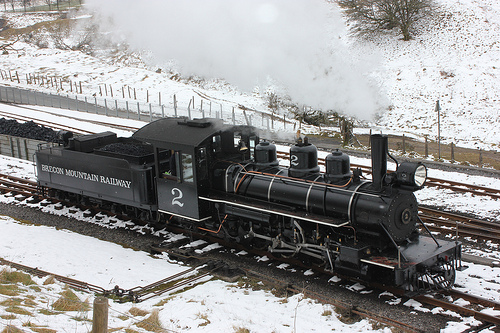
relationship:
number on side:
[168, 186, 186, 211] [154, 180, 198, 219]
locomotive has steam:
[36, 114, 465, 291] [69, 0, 393, 124]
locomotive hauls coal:
[36, 114, 465, 291] [92, 136, 173, 162]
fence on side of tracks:
[1, 86, 223, 120] [427, 175, 500, 200]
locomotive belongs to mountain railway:
[36, 114, 465, 291] [64, 165, 132, 190]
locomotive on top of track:
[36, 114, 465, 291] [0, 173, 499, 324]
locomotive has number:
[36, 114, 465, 291] [168, 186, 186, 211]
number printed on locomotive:
[168, 186, 186, 211] [36, 114, 465, 291]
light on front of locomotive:
[396, 162, 427, 190] [36, 114, 465, 291]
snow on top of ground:
[0, 220, 168, 285] [0, 255, 265, 331]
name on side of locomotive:
[64, 165, 132, 190] [36, 114, 465, 291]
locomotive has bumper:
[36, 114, 465, 291] [32, 144, 50, 196]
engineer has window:
[157, 148, 181, 183] [176, 151, 194, 184]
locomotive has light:
[36, 114, 465, 291] [396, 162, 427, 190]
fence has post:
[1, 86, 223, 120] [15, 70, 21, 86]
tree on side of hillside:
[337, 2, 437, 45] [343, 5, 499, 130]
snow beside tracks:
[0, 220, 168, 285] [427, 175, 500, 200]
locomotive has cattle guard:
[36, 114, 465, 291] [398, 246, 467, 295]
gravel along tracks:
[396, 309, 457, 333] [427, 295, 500, 327]